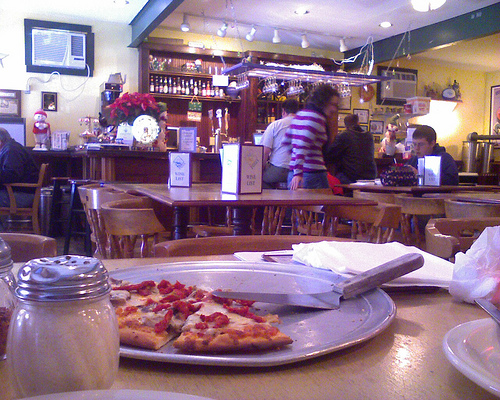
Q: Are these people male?
A: No, they are both male and female.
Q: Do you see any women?
A: Yes, there is a woman.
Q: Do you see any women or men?
A: Yes, there is a woman.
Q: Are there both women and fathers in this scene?
A: No, there is a woman but no fathers.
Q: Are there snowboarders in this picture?
A: No, there are no snowboarders.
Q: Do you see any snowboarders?
A: No, there are no snowboarders.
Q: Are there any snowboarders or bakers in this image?
A: No, there are no snowboarders or bakers.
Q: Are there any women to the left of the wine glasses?
A: Yes, there is a woman to the left of the wine glasses.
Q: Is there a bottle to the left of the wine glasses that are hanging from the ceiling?
A: No, there is a woman to the left of the wine glasses.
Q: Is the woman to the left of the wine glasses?
A: Yes, the woman is to the left of the wine glasses.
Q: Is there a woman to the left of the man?
A: Yes, there is a woman to the left of the man.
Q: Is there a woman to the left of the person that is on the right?
A: Yes, there is a woman to the left of the man.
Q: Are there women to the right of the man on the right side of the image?
A: No, the woman is to the left of the man.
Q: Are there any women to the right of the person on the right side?
A: No, the woman is to the left of the man.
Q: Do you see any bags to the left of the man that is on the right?
A: No, there is a woman to the left of the man.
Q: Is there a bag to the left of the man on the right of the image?
A: No, there is a woman to the left of the man.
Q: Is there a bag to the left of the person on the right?
A: No, there is a woman to the left of the man.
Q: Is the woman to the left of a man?
A: Yes, the woman is to the left of a man.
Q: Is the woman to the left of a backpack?
A: No, the woman is to the left of a man.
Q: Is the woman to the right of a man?
A: No, the woman is to the left of a man.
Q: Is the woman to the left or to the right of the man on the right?
A: The woman is to the left of the man.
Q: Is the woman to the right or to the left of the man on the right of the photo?
A: The woman is to the left of the man.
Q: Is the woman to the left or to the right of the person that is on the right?
A: The woman is to the left of the man.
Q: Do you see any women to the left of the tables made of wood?
A: Yes, there is a woman to the left of the tables.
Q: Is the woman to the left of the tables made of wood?
A: Yes, the woman is to the left of the tables.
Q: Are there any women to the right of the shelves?
A: Yes, there is a woman to the right of the shelves.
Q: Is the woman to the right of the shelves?
A: Yes, the woman is to the right of the shelves.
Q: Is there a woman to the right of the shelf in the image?
A: Yes, there is a woman to the right of the shelf.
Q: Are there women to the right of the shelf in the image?
A: Yes, there is a woman to the right of the shelf.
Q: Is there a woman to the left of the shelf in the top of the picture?
A: No, the woman is to the right of the shelf.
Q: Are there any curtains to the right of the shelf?
A: No, there is a woman to the right of the shelf.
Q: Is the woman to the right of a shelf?
A: Yes, the woman is to the right of a shelf.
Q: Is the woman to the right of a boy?
A: No, the woman is to the right of a shelf.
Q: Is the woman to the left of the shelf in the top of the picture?
A: No, the woman is to the right of the shelf.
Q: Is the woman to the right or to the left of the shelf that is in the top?
A: The woman is to the right of the shelf.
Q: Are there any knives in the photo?
A: No, there are no knives.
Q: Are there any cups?
A: No, there are no cups.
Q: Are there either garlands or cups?
A: No, there are no cups or garlands.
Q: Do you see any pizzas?
A: Yes, there is a pizza.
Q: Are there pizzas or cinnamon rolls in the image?
A: Yes, there is a pizza.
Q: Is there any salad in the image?
A: No, there is no salad.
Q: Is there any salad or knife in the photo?
A: No, there are no salad or knives.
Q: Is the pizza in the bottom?
A: Yes, the pizza is in the bottom of the image.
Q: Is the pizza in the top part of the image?
A: No, the pizza is in the bottom of the image.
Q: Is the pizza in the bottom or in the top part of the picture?
A: The pizza is in the bottom of the image.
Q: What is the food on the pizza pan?
A: The food is a pizza.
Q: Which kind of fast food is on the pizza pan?
A: The food is a pizza.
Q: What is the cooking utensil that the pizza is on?
A: The cooking utensil is a pizza pan.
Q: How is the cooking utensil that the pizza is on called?
A: The cooking utensil is a pizza pan.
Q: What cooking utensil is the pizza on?
A: The pizza is on the pizza pan.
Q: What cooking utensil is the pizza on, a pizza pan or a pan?
A: The pizza is on a pizza pan.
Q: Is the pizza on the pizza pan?
A: Yes, the pizza is on the pizza pan.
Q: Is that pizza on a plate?
A: No, the pizza is on the pizza pan.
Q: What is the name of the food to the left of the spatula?
A: The food is a pizza.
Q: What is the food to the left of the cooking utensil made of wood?
A: The food is a pizza.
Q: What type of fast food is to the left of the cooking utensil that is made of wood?
A: The food is a pizza.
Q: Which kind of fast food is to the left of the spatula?
A: The food is a pizza.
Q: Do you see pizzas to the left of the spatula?
A: Yes, there is a pizza to the left of the spatula.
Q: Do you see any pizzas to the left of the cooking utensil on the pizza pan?
A: Yes, there is a pizza to the left of the spatula.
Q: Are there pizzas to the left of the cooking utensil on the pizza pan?
A: Yes, there is a pizza to the left of the spatula.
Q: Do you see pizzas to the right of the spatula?
A: No, the pizza is to the left of the spatula.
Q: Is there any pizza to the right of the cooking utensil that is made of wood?
A: No, the pizza is to the left of the spatula.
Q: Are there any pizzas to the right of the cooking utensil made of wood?
A: No, the pizza is to the left of the spatula.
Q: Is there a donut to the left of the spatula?
A: No, there is a pizza to the left of the spatula.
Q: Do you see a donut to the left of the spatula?
A: No, there is a pizza to the left of the spatula.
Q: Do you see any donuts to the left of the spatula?
A: No, there is a pizza to the left of the spatula.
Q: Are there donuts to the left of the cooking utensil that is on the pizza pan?
A: No, there is a pizza to the left of the spatula.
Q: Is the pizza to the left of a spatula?
A: Yes, the pizza is to the left of a spatula.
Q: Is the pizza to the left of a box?
A: No, the pizza is to the left of a spatula.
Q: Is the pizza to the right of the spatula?
A: No, the pizza is to the left of the spatula.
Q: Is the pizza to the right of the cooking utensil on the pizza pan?
A: No, the pizza is to the left of the spatula.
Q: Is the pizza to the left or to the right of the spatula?
A: The pizza is to the left of the spatula.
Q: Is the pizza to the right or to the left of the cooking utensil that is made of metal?
A: The pizza is to the left of the spatula.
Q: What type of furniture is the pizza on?
A: The pizza is on the table.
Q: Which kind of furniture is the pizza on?
A: The pizza is on the table.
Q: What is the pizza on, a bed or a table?
A: The pizza is on a table.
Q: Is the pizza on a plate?
A: No, the pizza is on the table.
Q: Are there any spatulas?
A: Yes, there is a spatula.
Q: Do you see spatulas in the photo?
A: Yes, there is a spatula.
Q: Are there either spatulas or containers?
A: Yes, there is a spatula.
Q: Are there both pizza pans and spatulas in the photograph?
A: Yes, there are both a spatula and a pizza pan.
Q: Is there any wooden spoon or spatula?
A: Yes, there is a wood spatula.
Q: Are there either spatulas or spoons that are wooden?
A: Yes, the spatula is wooden.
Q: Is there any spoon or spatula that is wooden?
A: Yes, the spatula is wooden.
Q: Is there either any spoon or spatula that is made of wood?
A: Yes, the spatula is made of wood.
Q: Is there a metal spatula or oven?
A: Yes, there is a metal spatula.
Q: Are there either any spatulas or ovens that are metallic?
A: Yes, the spatula is metallic.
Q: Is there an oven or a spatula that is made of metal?
A: Yes, the spatula is made of metal.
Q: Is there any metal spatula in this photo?
A: Yes, there is a metal spatula.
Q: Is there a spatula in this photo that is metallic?
A: Yes, there is a spatula that is metallic.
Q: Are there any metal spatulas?
A: Yes, there is a spatula that is made of metal.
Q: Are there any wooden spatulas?
A: Yes, there is a wood spatula.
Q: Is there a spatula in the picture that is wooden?
A: Yes, there is a spatula that is wooden.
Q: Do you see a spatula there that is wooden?
A: Yes, there is a spatula that is wooden.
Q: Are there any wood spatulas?
A: Yes, there is a spatula that is made of wood.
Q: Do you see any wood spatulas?
A: Yes, there is a spatula that is made of wood.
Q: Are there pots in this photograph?
A: No, there are no pots.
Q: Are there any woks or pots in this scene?
A: No, there are no pots or woks.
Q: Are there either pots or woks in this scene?
A: No, there are no pots or woks.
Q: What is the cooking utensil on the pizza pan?
A: The cooking utensil is a spatula.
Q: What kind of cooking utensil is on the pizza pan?
A: The cooking utensil is a spatula.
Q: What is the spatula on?
A: The spatula is on the pizza pan.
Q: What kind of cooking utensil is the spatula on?
A: The spatula is on the pizza pan.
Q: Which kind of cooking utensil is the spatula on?
A: The spatula is on the pizza pan.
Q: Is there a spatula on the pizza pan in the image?
A: Yes, there is a spatula on the pizza pan.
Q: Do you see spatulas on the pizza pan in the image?
A: Yes, there is a spatula on the pizza pan.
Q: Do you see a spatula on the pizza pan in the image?
A: Yes, there is a spatula on the pizza pan.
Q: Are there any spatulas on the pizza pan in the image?
A: Yes, there is a spatula on the pizza pan.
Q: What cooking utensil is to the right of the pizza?
A: The cooking utensil is a spatula.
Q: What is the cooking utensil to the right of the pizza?
A: The cooking utensil is a spatula.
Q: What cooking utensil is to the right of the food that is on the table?
A: The cooking utensil is a spatula.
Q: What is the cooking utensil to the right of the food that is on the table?
A: The cooking utensil is a spatula.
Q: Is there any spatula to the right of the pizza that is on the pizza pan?
A: Yes, there is a spatula to the right of the pizza.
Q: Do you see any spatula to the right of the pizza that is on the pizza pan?
A: Yes, there is a spatula to the right of the pizza.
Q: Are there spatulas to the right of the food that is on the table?
A: Yes, there is a spatula to the right of the pizza.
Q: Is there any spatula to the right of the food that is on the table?
A: Yes, there is a spatula to the right of the pizza.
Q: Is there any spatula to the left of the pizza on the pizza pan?
A: No, the spatula is to the right of the pizza.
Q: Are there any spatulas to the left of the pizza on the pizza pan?
A: No, the spatula is to the right of the pizza.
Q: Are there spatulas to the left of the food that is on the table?
A: No, the spatula is to the right of the pizza.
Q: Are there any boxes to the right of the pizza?
A: No, there is a spatula to the right of the pizza.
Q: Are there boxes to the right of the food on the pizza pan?
A: No, there is a spatula to the right of the pizza.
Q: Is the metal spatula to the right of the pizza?
A: Yes, the spatula is to the right of the pizza.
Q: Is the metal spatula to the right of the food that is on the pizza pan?
A: Yes, the spatula is to the right of the pizza.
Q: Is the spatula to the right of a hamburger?
A: No, the spatula is to the right of the pizza.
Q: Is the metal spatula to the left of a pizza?
A: No, the spatula is to the right of a pizza.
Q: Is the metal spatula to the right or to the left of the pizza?
A: The spatula is to the right of the pizza.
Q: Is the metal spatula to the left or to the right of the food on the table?
A: The spatula is to the right of the pizza.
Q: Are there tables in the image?
A: Yes, there is a table.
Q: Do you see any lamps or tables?
A: Yes, there is a table.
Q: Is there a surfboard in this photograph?
A: No, there are no surfboards.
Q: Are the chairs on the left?
A: Yes, the chairs are on the left of the image.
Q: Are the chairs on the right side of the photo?
A: No, the chairs are on the left of the image.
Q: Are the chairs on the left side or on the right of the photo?
A: The chairs are on the left of the image.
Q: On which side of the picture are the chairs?
A: The chairs are on the left of the image.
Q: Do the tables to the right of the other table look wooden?
A: Yes, the tables are wooden.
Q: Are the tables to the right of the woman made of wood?
A: Yes, the tables are made of wood.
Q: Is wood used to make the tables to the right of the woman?
A: Yes, the tables are made of wood.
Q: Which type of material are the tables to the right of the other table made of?
A: The tables are made of wood.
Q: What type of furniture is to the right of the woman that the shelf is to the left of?
A: The pieces of furniture are tables.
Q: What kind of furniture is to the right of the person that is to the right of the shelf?
A: The pieces of furniture are tables.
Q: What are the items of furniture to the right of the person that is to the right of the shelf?
A: The pieces of furniture are tables.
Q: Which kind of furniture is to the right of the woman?
A: The pieces of furniture are tables.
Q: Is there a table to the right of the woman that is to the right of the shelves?
A: Yes, there are tables to the right of the woman.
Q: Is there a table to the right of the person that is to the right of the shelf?
A: Yes, there are tables to the right of the woman.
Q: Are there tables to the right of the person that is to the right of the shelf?
A: Yes, there are tables to the right of the woman.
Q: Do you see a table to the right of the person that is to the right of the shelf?
A: Yes, there are tables to the right of the woman.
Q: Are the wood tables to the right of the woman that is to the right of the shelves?
A: Yes, the tables are to the right of the woman.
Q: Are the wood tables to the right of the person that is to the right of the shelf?
A: Yes, the tables are to the right of the woman.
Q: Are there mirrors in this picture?
A: No, there are no mirrors.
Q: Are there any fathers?
A: No, there are no fathers.